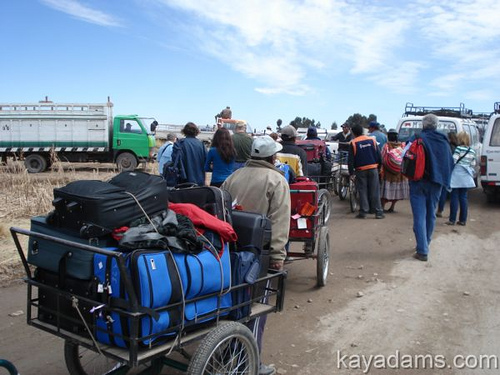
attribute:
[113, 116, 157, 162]
cab — green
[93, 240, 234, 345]
case — blue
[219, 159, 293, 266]
jacket — tan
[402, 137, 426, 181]
backpack — red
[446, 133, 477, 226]
person — travelling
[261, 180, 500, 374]
road — gray, murrum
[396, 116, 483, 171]
van — white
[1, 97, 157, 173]
truck — silver, large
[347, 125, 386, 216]
person — walking, standing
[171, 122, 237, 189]
couple — standing